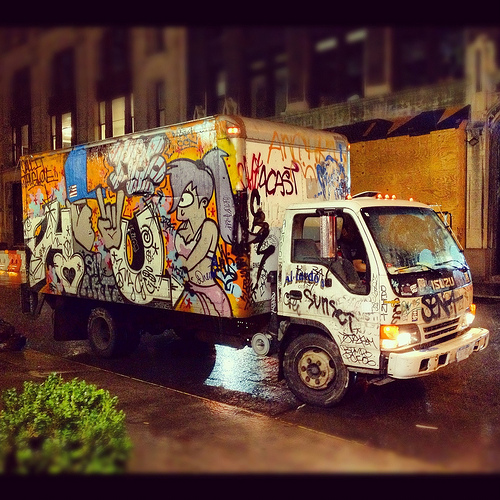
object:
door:
[275, 205, 382, 370]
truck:
[17, 113, 490, 407]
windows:
[97, 92, 135, 142]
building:
[0, 23, 499, 303]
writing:
[233, 153, 338, 202]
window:
[290, 211, 371, 293]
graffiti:
[387, 290, 457, 323]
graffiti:
[23, 156, 85, 190]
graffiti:
[171, 270, 244, 318]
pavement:
[0, 273, 499, 473]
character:
[23, 198, 85, 294]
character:
[60, 144, 124, 275]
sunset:
[302, 287, 356, 334]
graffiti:
[318, 157, 350, 199]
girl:
[165, 147, 235, 319]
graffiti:
[235, 142, 352, 195]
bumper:
[379, 326, 490, 379]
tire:
[282, 331, 350, 408]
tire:
[87, 306, 120, 357]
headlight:
[378, 323, 421, 350]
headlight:
[453, 302, 475, 331]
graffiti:
[82, 259, 113, 299]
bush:
[0, 369, 136, 475]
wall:
[349, 134, 464, 250]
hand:
[94, 185, 126, 252]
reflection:
[203, 337, 296, 399]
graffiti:
[284, 270, 320, 315]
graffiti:
[341, 332, 377, 366]